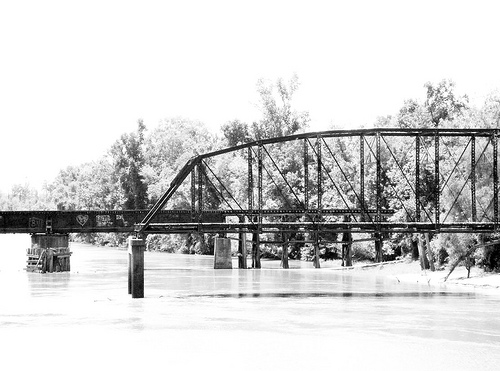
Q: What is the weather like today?
A: It is clear.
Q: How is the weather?
A: It is clear.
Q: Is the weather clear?
A: Yes, it is clear.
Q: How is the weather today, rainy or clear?
A: It is clear.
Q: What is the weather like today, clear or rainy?
A: It is clear.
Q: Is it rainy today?
A: No, it is clear.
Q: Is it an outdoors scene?
A: Yes, it is outdoors.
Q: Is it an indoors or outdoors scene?
A: It is outdoors.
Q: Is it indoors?
A: No, it is outdoors.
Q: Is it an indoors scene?
A: No, it is outdoors.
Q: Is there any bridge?
A: Yes, there is a bridge.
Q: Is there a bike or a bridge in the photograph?
A: Yes, there is a bridge.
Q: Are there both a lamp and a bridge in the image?
A: No, there is a bridge but no lamps.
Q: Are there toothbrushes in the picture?
A: No, there are no toothbrushes.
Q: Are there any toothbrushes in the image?
A: No, there are no toothbrushes.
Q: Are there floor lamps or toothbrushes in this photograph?
A: No, there are no toothbrushes or floor lamps.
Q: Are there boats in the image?
A: No, there are no boats.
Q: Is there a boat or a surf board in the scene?
A: No, there are no boats or surfboards.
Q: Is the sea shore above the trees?
A: Yes, the sea shore is above the trees.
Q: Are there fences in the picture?
A: Yes, there is a fence.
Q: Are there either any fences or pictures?
A: Yes, there is a fence.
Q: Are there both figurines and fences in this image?
A: No, there is a fence but no figurines.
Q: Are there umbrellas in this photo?
A: No, there are no umbrellas.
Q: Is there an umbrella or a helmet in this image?
A: No, there are no umbrellas or helmets.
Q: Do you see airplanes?
A: No, there are no airplanes.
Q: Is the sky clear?
A: Yes, the sky is clear.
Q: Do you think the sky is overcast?
A: No, the sky is clear.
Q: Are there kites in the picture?
A: No, there are no kites.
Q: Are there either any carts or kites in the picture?
A: No, there are no kites or carts.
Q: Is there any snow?
A: Yes, there is snow.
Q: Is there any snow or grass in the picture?
A: Yes, there is snow.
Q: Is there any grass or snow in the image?
A: Yes, there is snow.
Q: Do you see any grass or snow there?
A: Yes, there is snow.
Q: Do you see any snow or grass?
A: Yes, there is snow.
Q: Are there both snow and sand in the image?
A: No, there is snow but no sand.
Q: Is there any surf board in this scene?
A: No, there are no surfboards.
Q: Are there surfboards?
A: No, there are no surfboards.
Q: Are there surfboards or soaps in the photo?
A: No, there are no surfboards or soaps.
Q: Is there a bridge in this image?
A: Yes, there is a bridge.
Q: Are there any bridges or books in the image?
A: Yes, there is a bridge.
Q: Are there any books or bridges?
A: Yes, there is a bridge.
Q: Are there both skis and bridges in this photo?
A: No, there is a bridge but no skis.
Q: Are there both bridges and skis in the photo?
A: No, there is a bridge but no skis.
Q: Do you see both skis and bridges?
A: No, there is a bridge but no skis.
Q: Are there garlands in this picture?
A: No, there are no garlands.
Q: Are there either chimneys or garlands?
A: No, there are no garlands or chimneys.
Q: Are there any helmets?
A: No, there are no helmets.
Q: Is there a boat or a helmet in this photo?
A: No, there are no helmets or boats.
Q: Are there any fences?
A: Yes, there is a fence.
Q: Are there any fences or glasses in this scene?
A: Yes, there is a fence.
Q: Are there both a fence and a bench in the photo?
A: No, there is a fence but no benches.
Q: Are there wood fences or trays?
A: Yes, there is a wood fence.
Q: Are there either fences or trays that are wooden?
A: Yes, the fence is wooden.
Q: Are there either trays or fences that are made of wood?
A: Yes, the fence is made of wood.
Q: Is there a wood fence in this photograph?
A: Yes, there is a wood fence.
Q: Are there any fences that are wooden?
A: Yes, there is a fence that is wooden.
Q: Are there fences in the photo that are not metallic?
A: Yes, there is a wooden fence.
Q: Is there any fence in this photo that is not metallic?
A: Yes, there is a wooden fence.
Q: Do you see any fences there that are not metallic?
A: Yes, there is a wooden fence.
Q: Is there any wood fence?
A: Yes, there is a fence that is made of wood.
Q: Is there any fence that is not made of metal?
A: Yes, there is a fence that is made of wood.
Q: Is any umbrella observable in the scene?
A: No, there are no umbrellas.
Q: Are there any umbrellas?
A: No, there are no umbrellas.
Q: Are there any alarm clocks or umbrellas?
A: No, there are no umbrellas or alarm clocks.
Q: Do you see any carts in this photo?
A: No, there are no carts.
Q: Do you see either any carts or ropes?
A: No, there are no carts or ropes.